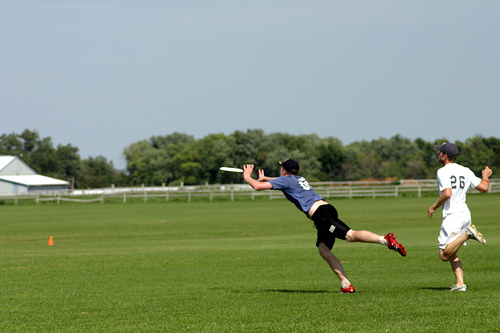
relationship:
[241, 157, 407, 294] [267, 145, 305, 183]
man has head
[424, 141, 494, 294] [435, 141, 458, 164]
man has a head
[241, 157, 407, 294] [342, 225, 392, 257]
man has a leg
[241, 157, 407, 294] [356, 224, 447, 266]
man has a leg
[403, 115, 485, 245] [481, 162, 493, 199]
man has an arm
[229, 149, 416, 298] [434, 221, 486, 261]
man has a leg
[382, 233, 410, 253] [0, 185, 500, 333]
shoe off field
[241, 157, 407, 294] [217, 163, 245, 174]
man playing frisbee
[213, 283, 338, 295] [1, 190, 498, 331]
shadow in grass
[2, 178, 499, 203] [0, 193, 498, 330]
wooden fence behind field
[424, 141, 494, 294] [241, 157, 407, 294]
man running after man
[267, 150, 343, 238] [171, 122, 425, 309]
shirt on man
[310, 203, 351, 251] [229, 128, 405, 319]
shorts on man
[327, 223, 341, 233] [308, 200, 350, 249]
logo on shorts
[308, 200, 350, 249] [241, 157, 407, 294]
shorts on man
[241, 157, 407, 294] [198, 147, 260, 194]
man playing frisbee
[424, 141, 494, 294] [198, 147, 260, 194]
man playing frisbee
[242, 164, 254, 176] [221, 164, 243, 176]
hand catching frisbee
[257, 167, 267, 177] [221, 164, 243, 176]
hand catching frisbee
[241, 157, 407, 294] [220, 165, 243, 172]
man catching frisbee